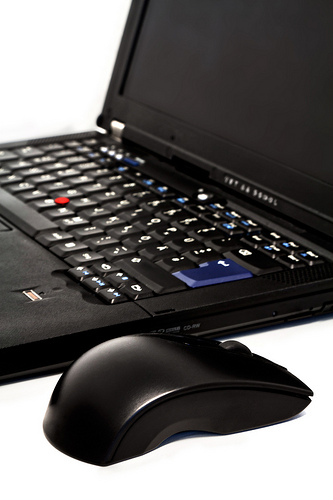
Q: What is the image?
A: Laptop.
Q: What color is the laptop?
A: Black.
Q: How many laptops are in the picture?
A: One.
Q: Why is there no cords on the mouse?
A: Wireless.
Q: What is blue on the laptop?
A: Enter key.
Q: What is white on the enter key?
A: Arrow.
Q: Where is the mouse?
A: Next to laptop.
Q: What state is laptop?
A: Open.